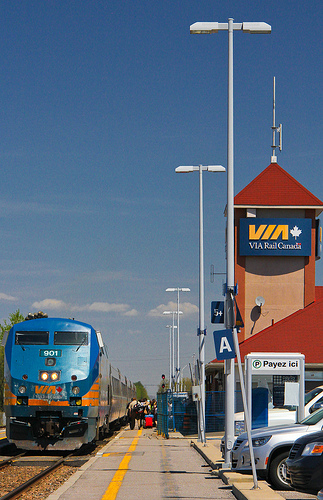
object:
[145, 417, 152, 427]
suit case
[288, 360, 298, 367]
ici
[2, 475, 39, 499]
track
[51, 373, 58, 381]
headlights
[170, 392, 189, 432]
phone booth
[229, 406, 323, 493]
car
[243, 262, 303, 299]
wall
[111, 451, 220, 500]
ground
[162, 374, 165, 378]
red lights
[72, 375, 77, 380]
red lights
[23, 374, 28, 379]
red lights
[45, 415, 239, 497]
platform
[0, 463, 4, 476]
gravel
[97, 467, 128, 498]
yellow line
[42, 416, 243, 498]
pavement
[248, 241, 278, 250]
via rail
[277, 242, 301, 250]
canada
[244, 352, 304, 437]
tan hat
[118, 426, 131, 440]
ground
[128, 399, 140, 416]
people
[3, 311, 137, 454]
train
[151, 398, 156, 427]
person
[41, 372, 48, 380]
headlights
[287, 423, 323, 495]
vehicle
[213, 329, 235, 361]
blue sign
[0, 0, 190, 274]
sky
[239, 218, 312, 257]
blue sign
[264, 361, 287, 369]
word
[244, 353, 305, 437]
phone booth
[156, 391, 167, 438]
fence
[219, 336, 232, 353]
letter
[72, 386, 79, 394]
headlight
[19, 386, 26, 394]
headlight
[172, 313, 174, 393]
pole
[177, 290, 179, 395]
pole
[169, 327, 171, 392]
pole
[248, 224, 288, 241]
via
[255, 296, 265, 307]
dish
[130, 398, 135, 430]
person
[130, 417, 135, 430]
pants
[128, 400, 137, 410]
shirt